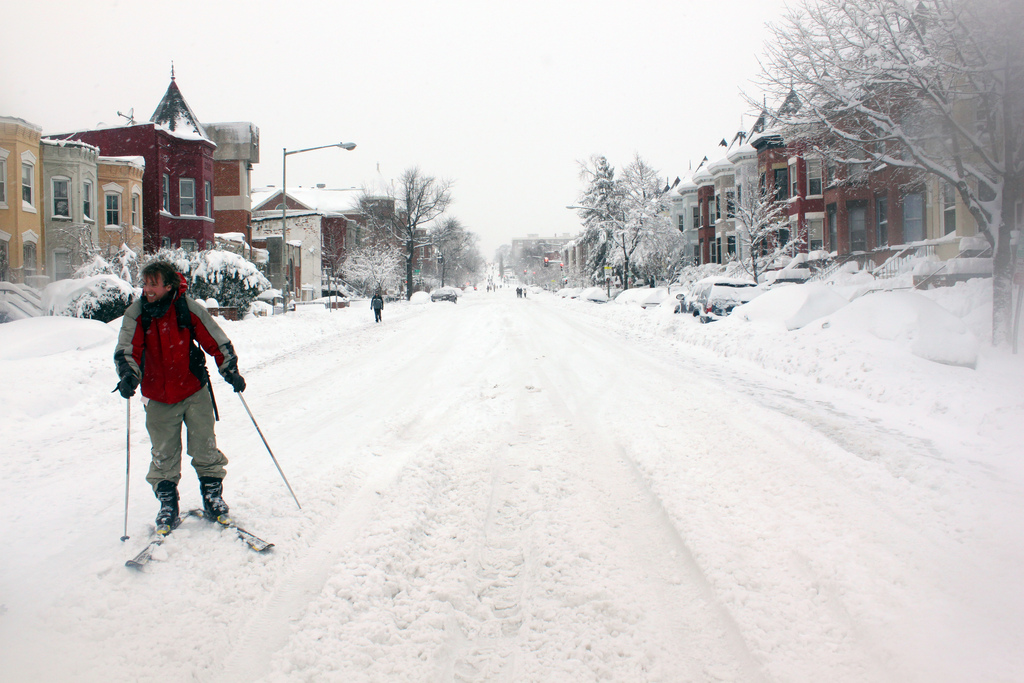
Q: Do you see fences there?
A: No, there are no fences.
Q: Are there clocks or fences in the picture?
A: No, there are no fences or clocks.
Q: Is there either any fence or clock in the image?
A: No, there are no fences or clocks.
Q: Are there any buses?
A: No, there are no buses.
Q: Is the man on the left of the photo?
A: Yes, the man is on the left of the image.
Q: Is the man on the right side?
A: No, the man is on the left of the image.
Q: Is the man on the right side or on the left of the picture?
A: The man is on the left of the image.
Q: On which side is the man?
A: The man is on the left of the image.